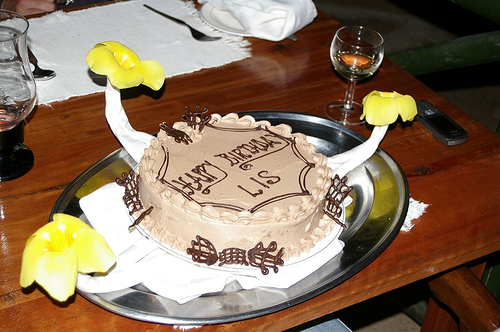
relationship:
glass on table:
[327, 23, 387, 125] [6, 4, 498, 324]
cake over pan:
[51, 118, 363, 274] [41, 103, 415, 330]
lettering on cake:
[174, 128, 301, 201] [124, 104, 358, 268]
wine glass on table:
[321, 22, 388, 124] [286, 67, 363, 122]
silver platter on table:
[131, 297, 236, 325] [407, 212, 481, 254]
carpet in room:
[364, 310, 416, 330] [2, 4, 498, 327]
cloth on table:
[15, 0, 250, 105] [6, 4, 498, 324]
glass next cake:
[322, 17, 390, 129] [82, 29, 424, 274]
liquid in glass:
[335, 54, 376, 77] [1, 15, 37, 141]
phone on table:
[410, 97, 470, 147] [6, 4, 498, 324]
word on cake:
[182, 163, 211, 192] [148, 92, 358, 289]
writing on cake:
[211, 127, 285, 174] [116, 108, 343, 266]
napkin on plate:
[215, 0, 329, 47] [193, 1, 262, 44]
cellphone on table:
[404, 97, 489, 154] [357, 43, 498, 235]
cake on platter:
[157, 120, 361, 205] [102, 129, 470, 280]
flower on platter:
[75, 34, 180, 194] [42, 99, 414, 324]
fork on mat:
[142, 0, 224, 44] [6, 4, 253, 109]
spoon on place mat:
[12, 27, 57, 84] [2, 0, 257, 112]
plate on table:
[197, 1, 255, 39] [6, 4, 498, 324]